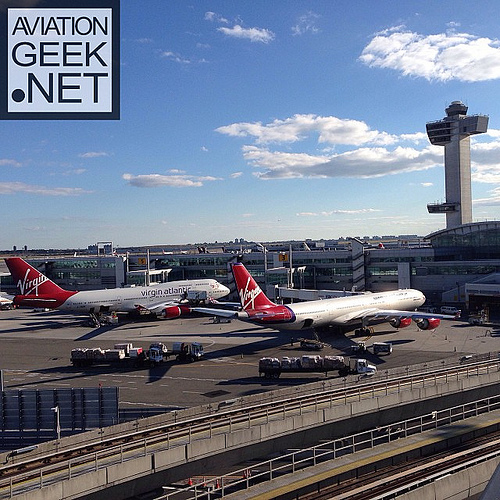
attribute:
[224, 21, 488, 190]
clouds — white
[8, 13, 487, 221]
sky — blue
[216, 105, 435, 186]
cloud — white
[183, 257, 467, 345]
plane — red, white, silver, parked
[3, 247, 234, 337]
plane — white, red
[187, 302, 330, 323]
stabilizer — horizontal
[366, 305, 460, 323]
wing — yellow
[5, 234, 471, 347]
planes — white, red